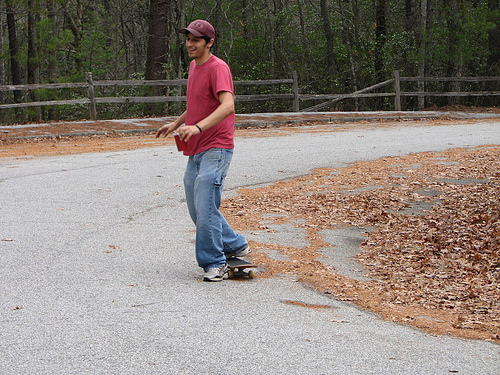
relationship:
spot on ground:
[280, 292, 339, 319] [0, 116, 497, 372]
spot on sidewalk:
[284, 148, 500, 375] [24, 147, 464, 357]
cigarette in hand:
[172, 126, 188, 142] [176, 120, 201, 145]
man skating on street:
[154, 18, 252, 282] [1, 122, 495, 373]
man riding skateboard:
[154, 18, 252, 282] [228, 252, 255, 283]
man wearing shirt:
[154, 18, 252, 282] [179, 57, 235, 153]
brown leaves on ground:
[352, 153, 500, 312] [341, 243, 422, 307]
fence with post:
[0, 79, 178, 109] [78, 72, 110, 124]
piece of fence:
[305, 67, 395, 111] [296, 65, 420, 123]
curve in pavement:
[214, 140, 498, 373] [0, 110, 498, 373]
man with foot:
[154, 18, 252, 282] [230, 240, 250, 258]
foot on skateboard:
[230, 240, 250, 258] [225, 257, 256, 278]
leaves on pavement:
[242, 143, 497, 319] [0, 110, 498, 373]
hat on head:
[179, 18, 216, 40] [184, 18, 217, 58]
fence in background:
[0, 71, 500, 126] [7, 10, 485, 117]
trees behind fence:
[1, 0, 498, 127] [7, 78, 485, 108]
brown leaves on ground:
[352, 179, 499, 276] [237, 131, 477, 361]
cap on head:
[179, 15, 219, 44] [172, 17, 220, 61]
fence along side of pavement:
[0, 71, 500, 126] [0, 110, 498, 373]